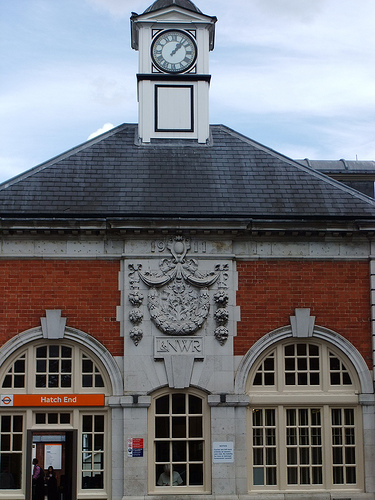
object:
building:
[0, 1, 374, 500]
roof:
[0, 124, 375, 231]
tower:
[130, 0, 218, 144]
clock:
[151, 29, 197, 74]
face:
[154, 30, 195, 70]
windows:
[329, 402, 366, 489]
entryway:
[26, 429, 77, 497]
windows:
[0, 353, 27, 389]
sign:
[13, 393, 105, 406]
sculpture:
[116, 235, 241, 395]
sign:
[127, 437, 144, 457]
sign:
[212, 442, 234, 464]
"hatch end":
[41, 397, 76, 403]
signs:
[13, 394, 235, 464]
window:
[149, 383, 213, 495]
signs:
[127, 437, 235, 463]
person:
[157, 464, 183, 485]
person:
[32, 458, 45, 499]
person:
[45, 466, 56, 500]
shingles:
[0, 124, 371, 220]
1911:
[151, 241, 206, 253]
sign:
[157, 340, 201, 352]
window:
[245, 335, 366, 495]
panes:
[285, 344, 319, 356]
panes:
[330, 358, 341, 385]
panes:
[253, 410, 275, 426]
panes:
[288, 467, 319, 483]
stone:
[290, 308, 316, 338]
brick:
[266, 291, 278, 294]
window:
[2, 411, 23, 453]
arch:
[234, 325, 373, 395]